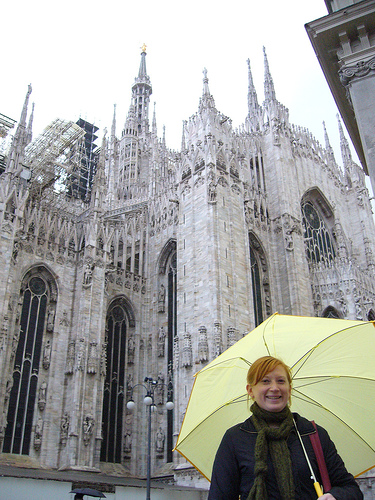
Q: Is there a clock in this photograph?
A: No, there are no clocks.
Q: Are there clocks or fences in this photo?
A: No, there are no clocks or fences.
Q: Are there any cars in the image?
A: No, there are no cars.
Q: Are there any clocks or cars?
A: No, there are no cars or clocks.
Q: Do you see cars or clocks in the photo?
A: No, there are no cars or clocks.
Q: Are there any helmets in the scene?
A: No, there are no helmets.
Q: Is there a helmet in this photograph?
A: No, there are no helmets.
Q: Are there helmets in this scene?
A: No, there are no helmets.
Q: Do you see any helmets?
A: No, there are no helmets.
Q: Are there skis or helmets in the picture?
A: No, there are no helmets or skis.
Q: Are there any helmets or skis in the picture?
A: No, there are no helmets or skis.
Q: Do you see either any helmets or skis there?
A: No, there are no helmets or skis.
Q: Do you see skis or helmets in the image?
A: No, there are no helmets or skis.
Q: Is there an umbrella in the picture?
A: Yes, there is an umbrella.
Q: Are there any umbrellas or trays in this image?
A: Yes, there is an umbrella.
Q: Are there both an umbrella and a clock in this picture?
A: No, there is an umbrella but no clocks.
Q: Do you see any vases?
A: No, there are no vases.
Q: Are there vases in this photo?
A: No, there are no vases.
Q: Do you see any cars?
A: No, there are no cars.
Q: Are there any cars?
A: No, there are no cars.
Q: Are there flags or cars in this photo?
A: No, there are no cars or flags.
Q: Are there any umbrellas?
A: Yes, there is an umbrella.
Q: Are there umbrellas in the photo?
A: Yes, there is an umbrella.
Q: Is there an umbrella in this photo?
A: Yes, there is an umbrella.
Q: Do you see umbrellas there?
A: Yes, there is an umbrella.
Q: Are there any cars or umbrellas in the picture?
A: Yes, there is an umbrella.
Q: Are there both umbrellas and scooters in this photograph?
A: No, there is an umbrella but no scooters.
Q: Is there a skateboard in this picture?
A: No, there are no skateboards.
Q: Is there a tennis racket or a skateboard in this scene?
A: No, there are no skateboards or rackets.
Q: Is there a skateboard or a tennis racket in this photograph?
A: No, there are no skateboards or rackets.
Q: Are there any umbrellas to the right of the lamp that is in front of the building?
A: Yes, there is an umbrella to the right of the lamp.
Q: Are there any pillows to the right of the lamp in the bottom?
A: No, there is an umbrella to the right of the lamp.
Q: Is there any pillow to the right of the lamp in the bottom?
A: No, there is an umbrella to the right of the lamp.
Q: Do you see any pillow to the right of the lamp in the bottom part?
A: No, there is an umbrella to the right of the lamp.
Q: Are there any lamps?
A: Yes, there is a lamp.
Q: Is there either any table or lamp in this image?
A: Yes, there is a lamp.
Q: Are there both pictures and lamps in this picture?
A: No, there is a lamp but no pictures.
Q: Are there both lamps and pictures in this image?
A: No, there is a lamp but no pictures.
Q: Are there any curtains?
A: No, there are no curtains.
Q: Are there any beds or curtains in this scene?
A: No, there are no curtains or beds.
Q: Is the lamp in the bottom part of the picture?
A: Yes, the lamp is in the bottom of the image.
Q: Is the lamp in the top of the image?
A: No, the lamp is in the bottom of the image.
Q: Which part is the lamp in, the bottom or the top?
A: The lamp is in the bottom of the image.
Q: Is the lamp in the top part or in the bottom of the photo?
A: The lamp is in the bottom of the image.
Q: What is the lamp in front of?
A: The lamp is in front of the building.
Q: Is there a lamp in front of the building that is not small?
A: Yes, there is a lamp in front of the building.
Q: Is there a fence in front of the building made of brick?
A: No, there is a lamp in front of the building.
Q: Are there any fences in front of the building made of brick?
A: No, there is a lamp in front of the building.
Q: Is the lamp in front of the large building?
A: Yes, the lamp is in front of the building.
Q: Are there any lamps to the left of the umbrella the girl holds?
A: Yes, there is a lamp to the left of the umbrella.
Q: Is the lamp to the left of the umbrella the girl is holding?
A: Yes, the lamp is to the left of the umbrella.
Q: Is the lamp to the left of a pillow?
A: No, the lamp is to the left of the umbrella.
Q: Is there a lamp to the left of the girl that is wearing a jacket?
A: Yes, there is a lamp to the left of the girl.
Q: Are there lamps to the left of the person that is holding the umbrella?
A: Yes, there is a lamp to the left of the girl.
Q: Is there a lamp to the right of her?
A: No, the lamp is to the left of the girl.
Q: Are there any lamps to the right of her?
A: No, the lamp is to the left of the girl.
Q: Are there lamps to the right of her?
A: No, the lamp is to the left of the girl.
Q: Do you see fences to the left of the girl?
A: No, there is a lamp to the left of the girl.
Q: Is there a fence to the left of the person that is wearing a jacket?
A: No, there is a lamp to the left of the girl.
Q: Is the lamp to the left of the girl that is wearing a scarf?
A: Yes, the lamp is to the left of the girl.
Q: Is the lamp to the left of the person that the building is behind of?
A: Yes, the lamp is to the left of the girl.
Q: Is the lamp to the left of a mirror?
A: No, the lamp is to the left of the girl.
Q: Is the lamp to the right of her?
A: No, the lamp is to the left of the girl.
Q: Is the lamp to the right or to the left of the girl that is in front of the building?
A: The lamp is to the left of the girl.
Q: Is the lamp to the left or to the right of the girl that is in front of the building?
A: The lamp is to the left of the girl.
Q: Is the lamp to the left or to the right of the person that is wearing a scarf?
A: The lamp is to the left of the girl.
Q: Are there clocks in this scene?
A: No, there are no clocks.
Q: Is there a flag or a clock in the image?
A: No, there are no clocks or flags.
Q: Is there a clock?
A: No, there are no clocks.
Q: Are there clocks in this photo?
A: No, there are no clocks.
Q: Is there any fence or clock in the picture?
A: No, there are no clocks or fences.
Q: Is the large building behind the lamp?
A: Yes, the building is behind the lamp.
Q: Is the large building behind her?
A: Yes, the building is behind the girl.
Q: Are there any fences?
A: No, there are no fences.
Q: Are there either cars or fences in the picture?
A: No, there are no fences or cars.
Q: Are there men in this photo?
A: No, there are no men.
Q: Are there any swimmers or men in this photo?
A: No, there are no men or swimmers.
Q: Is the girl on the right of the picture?
A: Yes, the girl is on the right of the image.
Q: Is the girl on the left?
A: No, the girl is on the right of the image.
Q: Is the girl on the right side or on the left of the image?
A: The girl is on the right of the image.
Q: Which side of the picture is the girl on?
A: The girl is on the right of the image.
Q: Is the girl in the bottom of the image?
A: Yes, the girl is in the bottom of the image.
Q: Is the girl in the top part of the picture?
A: No, the girl is in the bottom of the image.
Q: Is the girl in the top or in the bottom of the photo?
A: The girl is in the bottom of the image.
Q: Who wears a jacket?
A: The girl wears a jacket.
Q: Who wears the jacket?
A: The girl wears a jacket.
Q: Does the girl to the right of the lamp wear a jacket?
A: Yes, the girl wears a jacket.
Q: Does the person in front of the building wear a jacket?
A: Yes, the girl wears a jacket.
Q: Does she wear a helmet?
A: No, the girl wears a jacket.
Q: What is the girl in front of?
A: The girl is in front of the building.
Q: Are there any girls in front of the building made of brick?
A: Yes, there is a girl in front of the building.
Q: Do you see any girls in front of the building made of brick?
A: Yes, there is a girl in front of the building.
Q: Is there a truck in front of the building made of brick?
A: No, there is a girl in front of the building.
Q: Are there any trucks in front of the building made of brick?
A: No, there is a girl in front of the building.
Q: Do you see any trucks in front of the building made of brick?
A: No, there is a girl in front of the building.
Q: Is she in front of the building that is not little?
A: Yes, the girl is in front of the building.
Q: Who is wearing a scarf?
A: The girl is wearing a scarf.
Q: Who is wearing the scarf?
A: The girl is wearing a scarf.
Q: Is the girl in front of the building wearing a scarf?
A: Yes, the girl is wearing a scarf.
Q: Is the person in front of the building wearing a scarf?
A: Yes, the girl is wearing a scarf.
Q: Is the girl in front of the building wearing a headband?
A: No, the girl is wearing a scarf.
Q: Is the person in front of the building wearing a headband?
A: No, the girl is wearing a scarf.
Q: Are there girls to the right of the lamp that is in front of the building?
A: Yes, there is a girl to the right of the lamp.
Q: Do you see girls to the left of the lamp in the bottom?
A: No, the girl is to the right of the lamp.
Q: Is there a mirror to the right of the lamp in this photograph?
A: No, there is a girl to the right of the lamp.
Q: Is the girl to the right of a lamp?
A: Yes, the girl is to the right of a lamp.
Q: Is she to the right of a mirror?
A: No, the girl is to the right of a lamp.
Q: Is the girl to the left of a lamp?
A: No, the girl is to the right of a lamp.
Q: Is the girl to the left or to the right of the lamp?
A: The girl is to the right of the lamp.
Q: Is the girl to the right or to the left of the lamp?
A: The girl is to the right of the lamp.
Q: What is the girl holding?
A: The girl is holding the umbrella.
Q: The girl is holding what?
A: The girl is holding the umbrella.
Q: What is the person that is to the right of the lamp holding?
A: The girl is holding the umbrella.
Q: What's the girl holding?
A: The girl is holding the umbrella.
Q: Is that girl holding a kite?
A: No, the girl is holding the umbrella.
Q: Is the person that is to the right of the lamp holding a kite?
A: No, the girl is holding the umbrella.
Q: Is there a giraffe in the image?
A: No, there are no giraffes.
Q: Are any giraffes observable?
A: No, there are no giraffes.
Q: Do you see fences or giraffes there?
A: No, there are no giraffes or fences.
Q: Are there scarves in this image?
A: Yes, there is a scarf.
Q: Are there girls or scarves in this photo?
A: Yes, there is a scarf.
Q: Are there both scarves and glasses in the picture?
A: No, there is a scarf but no glasses.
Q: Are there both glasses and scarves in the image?
A: No, there is a scarf but no glasses.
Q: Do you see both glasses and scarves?
A: No, there is a scarf but no glasses.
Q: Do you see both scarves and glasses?
A: No, there is a scarf but no glasses.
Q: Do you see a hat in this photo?
A: No, there are no hats.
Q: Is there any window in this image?
A: Yes, there is a window.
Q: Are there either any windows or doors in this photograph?
A: Yes, there is a window.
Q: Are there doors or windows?
A: Yes, there is a window.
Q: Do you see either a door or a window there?
A: Yes, there is a window.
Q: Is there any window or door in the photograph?
A: Yes, there is a window.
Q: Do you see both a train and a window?
A: No, there is a window but no trains.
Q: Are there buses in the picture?
A: No, there are no buses.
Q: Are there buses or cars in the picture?
A: No, there are no buses or cars.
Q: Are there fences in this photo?
A: No, there are no fences.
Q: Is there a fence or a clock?
A: No, there are no fences or clocks.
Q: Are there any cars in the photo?
A: No, there are no cars.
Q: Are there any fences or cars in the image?
A: No, there are no cars or fences.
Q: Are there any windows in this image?
A: Yes, there is a window.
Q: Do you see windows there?
A: Yes, there is a window.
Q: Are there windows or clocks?
A: Yes, there is a window.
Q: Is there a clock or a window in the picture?
A: Yes, there is a window.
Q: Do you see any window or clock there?
A: Yes, there is a window.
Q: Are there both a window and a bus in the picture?
A: No, there is a window but no buses.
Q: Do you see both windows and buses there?
A: No, there is a window but no buses.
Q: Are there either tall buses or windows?
A: Yes, there is a tall window.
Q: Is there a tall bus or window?
A: Yes, there is a tall window.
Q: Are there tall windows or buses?
A: Yes, there is a tall window.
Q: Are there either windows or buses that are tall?
A: Yes, the window is tall.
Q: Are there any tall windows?
A: Yes, there is a tall window.